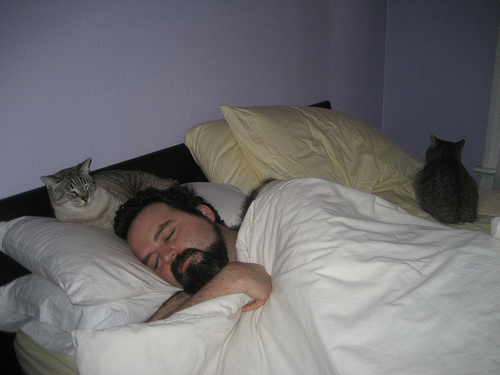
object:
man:
[112, 174, 500, 371]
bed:
[0, 100, 500, 375]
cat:
[40, 157, 179, 229]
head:
[114, 184, 227, 300]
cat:
[413, 133, 479, 224]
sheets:
[183, 97, 498, 220]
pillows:
[184, 119, 269, 216]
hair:
[114, 184, 225, 239]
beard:
[170, 223, 228, 295]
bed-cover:
[70, 176, 500, 375]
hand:
[220, 261, 273, 313]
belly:
[84, 202, 116, 228]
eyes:
[83, 183, 91, 192]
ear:
[77, 156, 92, 174]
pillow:
[0, 181, 245, 306]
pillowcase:
[221, 96, 435, 208]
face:
[128, 200, 228, 293]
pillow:
[1, 273, 180, 352]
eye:
[164, 228, 177, 242]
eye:
[153, 253, 162, 270]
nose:
[156, 245, 178, 265]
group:
[4, 174, 261, 352]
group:
[184, 96, 426, 214]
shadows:
[256, 11, 392, 105]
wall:
[5, 0, 500, 200]